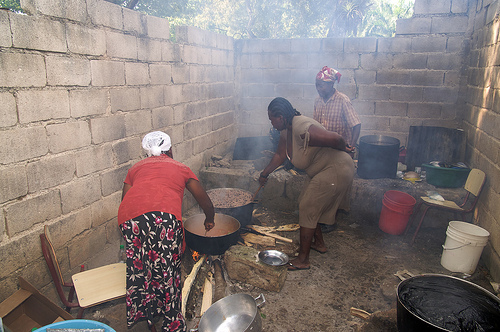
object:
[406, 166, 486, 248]
chair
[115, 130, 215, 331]
lady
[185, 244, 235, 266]
stove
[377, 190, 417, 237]
red bucket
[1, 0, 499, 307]
wall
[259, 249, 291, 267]
plate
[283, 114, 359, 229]
brown dress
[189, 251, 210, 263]
fire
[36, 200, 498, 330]
ground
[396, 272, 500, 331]
pot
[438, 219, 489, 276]
buckets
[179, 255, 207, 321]
logs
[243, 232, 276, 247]
logs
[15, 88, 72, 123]
cement blocks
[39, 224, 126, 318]
chair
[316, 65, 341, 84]
head scarf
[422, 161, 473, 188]
trough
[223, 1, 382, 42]
tree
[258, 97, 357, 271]
woman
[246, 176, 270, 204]
utensil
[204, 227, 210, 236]
utensil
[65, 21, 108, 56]
cinder block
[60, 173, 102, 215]
cinder block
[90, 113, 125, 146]
cinder block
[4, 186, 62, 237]
cinder block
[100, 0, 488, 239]
smoke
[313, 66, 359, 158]
person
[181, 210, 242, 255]
pot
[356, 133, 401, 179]
pot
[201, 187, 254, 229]
pot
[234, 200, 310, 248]
wood stove